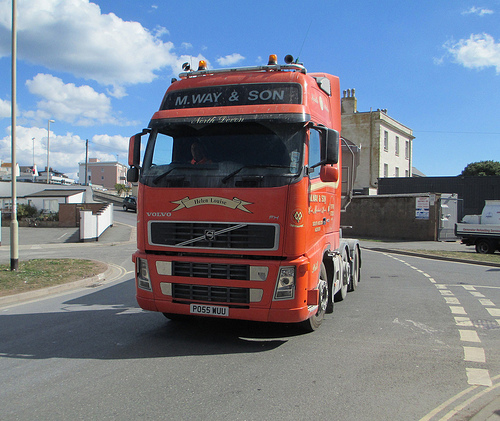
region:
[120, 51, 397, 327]
truck on the street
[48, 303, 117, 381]
shadow on the ground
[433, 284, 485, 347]
white marks on the ground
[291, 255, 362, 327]
tires on the truck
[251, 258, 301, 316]
light on the truck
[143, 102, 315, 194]
front window on truck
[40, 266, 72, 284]
grass next to truck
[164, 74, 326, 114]
words on the top of the truck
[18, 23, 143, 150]
clouds in the sky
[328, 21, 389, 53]
blue sky above the land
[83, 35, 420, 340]
Truck on the road.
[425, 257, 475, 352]
White lines on the road.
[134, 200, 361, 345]
Lights on the truck.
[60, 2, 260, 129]
White clouds in the sky.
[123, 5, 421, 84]
Blue sky with white clouds.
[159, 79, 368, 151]
Name on the truck.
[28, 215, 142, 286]
Grass on the curb.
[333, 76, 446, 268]
Building in the background.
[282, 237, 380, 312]
Wheels on the truck.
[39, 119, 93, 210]
Light pole in the background.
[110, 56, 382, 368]
Red truck in the street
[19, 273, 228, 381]
Shadows cast on the pavement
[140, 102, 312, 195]
Front window of the truck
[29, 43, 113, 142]
White clouds in the sky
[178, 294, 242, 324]
White license plate on the truck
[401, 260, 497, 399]
White lines on the pavement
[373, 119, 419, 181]
Windows on a white building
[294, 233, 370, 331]
Tires on the truck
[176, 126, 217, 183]
Man sitting inside the truck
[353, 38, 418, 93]
Sky is bright blue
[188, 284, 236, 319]
part of a plate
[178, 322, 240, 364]
edge of a shade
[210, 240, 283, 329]
part of a truck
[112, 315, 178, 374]
part of a shade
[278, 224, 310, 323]
edge of a truck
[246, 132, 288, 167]
part of a window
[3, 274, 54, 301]
edge of a road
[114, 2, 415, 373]
semi traveling down road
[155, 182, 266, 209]
gold emblem on semi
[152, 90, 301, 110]
company name on roof of semi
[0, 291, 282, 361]
shadows cast on ground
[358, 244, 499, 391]
white lines on road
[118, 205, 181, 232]
volvo logo on front of semi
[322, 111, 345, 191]
large mirrors on semi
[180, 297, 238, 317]
license plate on front of semi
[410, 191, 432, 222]
sign on retaining wall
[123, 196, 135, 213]
car traveling down street